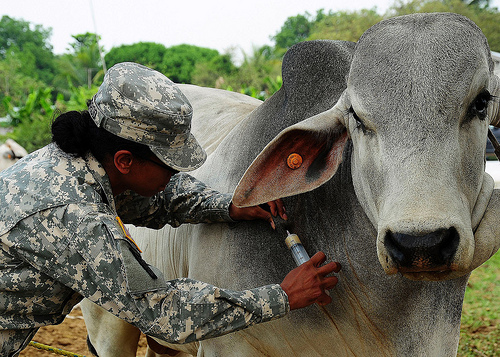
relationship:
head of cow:
[232, 12, 499, 279] [79, 14, 499, 356]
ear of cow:
[229, 101, 350, 210] [79, 14, 499, 356]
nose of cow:
[379, 223, 463, 279] [79, 14, 499, 356]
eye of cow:
[472, 88, 489, 118] [79, 14, 499, 356]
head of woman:
[47, 57, 204, 200] [1, 60, 342, 356]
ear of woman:
[109, 145, 134, 177] [1, 60, 342, 356]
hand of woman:
[283, 249, 342, 312] [1, 60, 342, 356]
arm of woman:
[70, 216, 288, 345] [1, 60, 342, 356]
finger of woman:
[320, 261, 345, 273] [1, 60, 342, 356]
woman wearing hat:
[1, 60, 342, 356] [85, 60, 208, 174]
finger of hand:
[320, 261, 345, 273] [283, 249, 342, 312]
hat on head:
[85, 60, 208, 174] [47, 57, 204, 200]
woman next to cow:
[1, 60, 342, 356] [79, 14, 499, 356]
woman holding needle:
[1, 60, 342, 356] [270, 213, 332, 305]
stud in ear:
[285, 150, 304, 172] [229, 101, 350, 210]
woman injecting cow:
[1, 60, 342, 356] [79, 14, 499, 356]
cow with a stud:
[79, 14, 499, 356] [285, 150, 304, 172]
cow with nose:
[79, 14, 499, 356] [379, 223, 463, 279]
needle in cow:
[270, 213, 332, 305] [79, 14, 499, 356]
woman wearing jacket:
[1, 60, 342, 356] [2, 140, 292, 357]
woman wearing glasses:
[1, 60, 342, 356] [136, 154, 180, 176]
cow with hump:
[79, 14, 499, 356] [273, 39, 351, 97]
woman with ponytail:
[1, 60, 342, 356] [48, 110, 91, 160]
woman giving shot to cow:
[1, 60, 342, 356] [79, 14, 499, 356]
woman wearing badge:
[1, 60, 342, 356] [113, 213, 142, 251]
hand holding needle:
[283, 249, 342, 312] [270, 213, 332, 305]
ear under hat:
[109, 145, 134, 177] [80, 56, 222, 173]